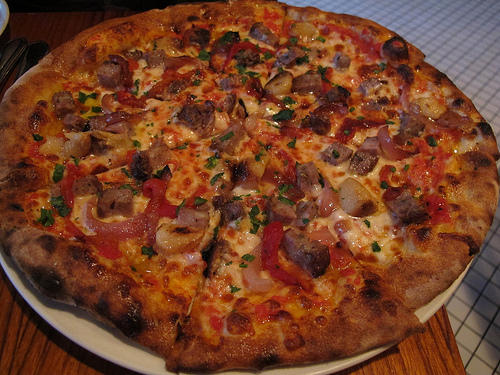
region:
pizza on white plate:
[2, 3, 498, 371]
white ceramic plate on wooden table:
[1, 250, 483, 372]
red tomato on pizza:
[52, 158, 82, 213]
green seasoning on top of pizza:
[25, 153, 79, 232]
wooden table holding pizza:
[2, 9, 469, 373]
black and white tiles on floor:
[287, 1, 498, 372]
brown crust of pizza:
[16, 133, 497, 372]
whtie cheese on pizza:
[229, 231, 256, 260]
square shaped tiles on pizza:
[460, 301, 493, 341]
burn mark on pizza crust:
[107, 298, 157, 344]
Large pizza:
[0, 2, 497, 373]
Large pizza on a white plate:
[0, 0, 498, 372]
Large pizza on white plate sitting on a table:
[4, 3, 498, 373]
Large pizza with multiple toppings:
[5, 5, 497, 371]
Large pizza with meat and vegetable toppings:
[8, 0, 493, 370]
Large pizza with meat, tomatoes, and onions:
[13, 2, 495, 372]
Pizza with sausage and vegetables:
[7, 2, 496, 368]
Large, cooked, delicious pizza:
[0, 11, 497, 366]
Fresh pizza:
[1, 0, 492, 367]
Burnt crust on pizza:
[8, 227, 171, 346]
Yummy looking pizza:
[4, 2, 498, 371]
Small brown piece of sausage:
[97, 186, 137, 222]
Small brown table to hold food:
[5, 0, 470, 374]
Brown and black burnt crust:
[3, 213, 185, 364]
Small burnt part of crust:
[253, 350, 283, 373]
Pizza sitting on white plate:
[0, 3, 499, 373]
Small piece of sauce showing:
[258, 215, 305, 295]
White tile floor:
[305, 0, 497, 372]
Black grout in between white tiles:
[290, 3, 499, 374]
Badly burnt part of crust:
[116, 303, 144, 342]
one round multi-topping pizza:
[10, 5, 499, 373]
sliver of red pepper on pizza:
[258, 218, 302, 301]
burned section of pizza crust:
[27, 258, 74, 303]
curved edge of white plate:
[28, 314, 101, 374]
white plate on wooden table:
[4, 319, 104, 374]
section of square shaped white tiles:
[426, 13, 495, 60]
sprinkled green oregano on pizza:
[192, 151, 300, 227]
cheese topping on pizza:
[350, 220, 399, 265]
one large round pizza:
[8, 9, 495, 374]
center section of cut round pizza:
[194, 88, 306, 184]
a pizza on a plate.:
[0, 3, 498, 374]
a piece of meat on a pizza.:
[274, 150, 348, 201]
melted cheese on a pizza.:
[352, 228, 399, 254]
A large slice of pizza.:
[0, 122, 254, 345]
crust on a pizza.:
[167, 283, 412, 374]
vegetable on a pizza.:
[324, 165, 386, 228]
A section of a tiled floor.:
[449, 250, 498, 358]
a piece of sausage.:
[177, 93, 228, 142]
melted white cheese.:
[221, 196, 273, 287]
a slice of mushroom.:
[150, 197, 223, 265]